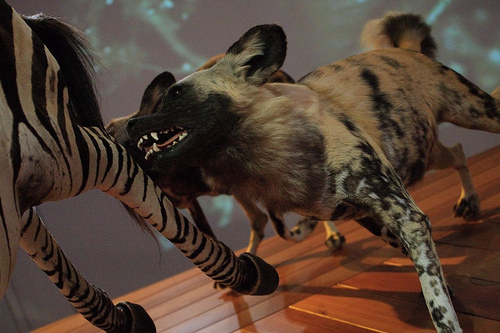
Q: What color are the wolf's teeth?
A: White.